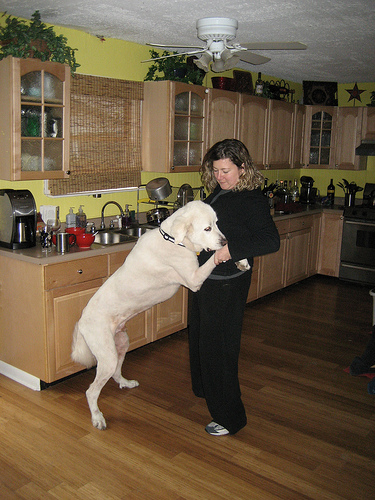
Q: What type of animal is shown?
A: Dog.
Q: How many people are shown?
A: One.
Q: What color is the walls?
A: Yellow.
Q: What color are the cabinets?
A: Brown.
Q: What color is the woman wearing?
A: Black.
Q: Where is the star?
A: Wall.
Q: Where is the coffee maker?
A: Counter.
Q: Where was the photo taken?
A: In a kitchen.